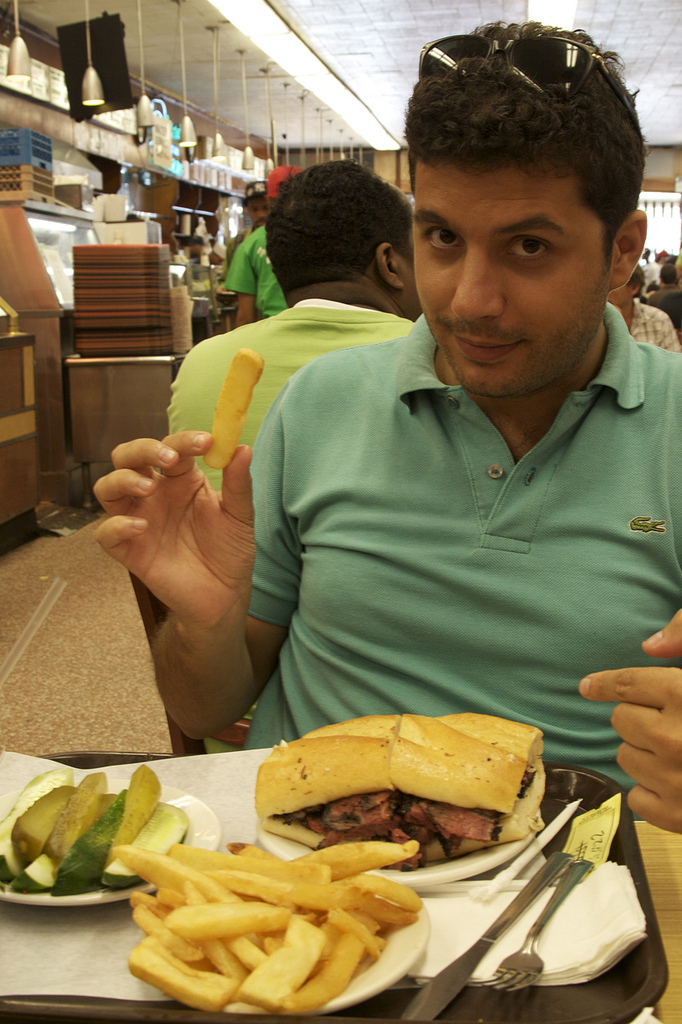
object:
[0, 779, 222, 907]
plate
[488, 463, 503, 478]
button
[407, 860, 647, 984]
napkin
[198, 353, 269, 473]
french fry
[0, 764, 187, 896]
pickles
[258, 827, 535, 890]
plate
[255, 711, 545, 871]
sandwich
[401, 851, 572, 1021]
knife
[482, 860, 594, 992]
fork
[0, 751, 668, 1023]
tray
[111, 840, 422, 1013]
french fry's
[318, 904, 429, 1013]
plate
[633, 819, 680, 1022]
table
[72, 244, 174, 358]
trays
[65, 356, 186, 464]
cart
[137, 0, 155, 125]
hanging lights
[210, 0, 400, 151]
ceiling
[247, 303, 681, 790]
shirt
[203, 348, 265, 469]
french fry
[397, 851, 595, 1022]
utensil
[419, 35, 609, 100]
glasses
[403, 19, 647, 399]
head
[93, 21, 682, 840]
man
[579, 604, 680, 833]
fingers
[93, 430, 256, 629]
hand